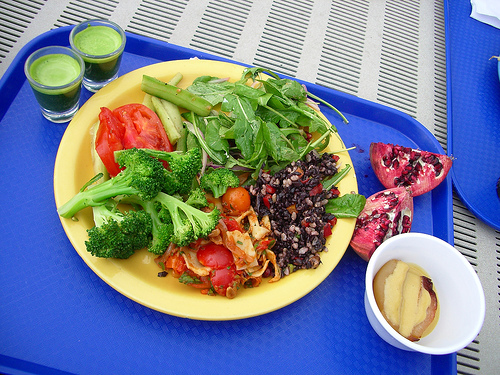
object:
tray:
[442, 0, 499, 231]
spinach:
[179, 66, 367, 219]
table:
[255, 1, 389, 56]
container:
[69, 19, 127, 93]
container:
[23, 44, 85, 123]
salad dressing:
[73, 25, 123, 85]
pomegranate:
[350, 184, 413, 262]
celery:
[140, 74, 214, 144]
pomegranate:
[368, 140, 453, 195]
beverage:
[27, 52, 82, 114]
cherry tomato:
[221, 186, 251, 216]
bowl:
[363, 232, 485, 353]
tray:
[0, 24, 456, 375]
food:
[56, 66, 453, 340]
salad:
[56, 66, 366, 299]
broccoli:
[56, 147, 239, 259]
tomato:
[95, 102, 175, 177]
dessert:
[371, 258, 437, 342]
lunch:
[24, 24, 452, 341]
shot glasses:
[24, 18, 126, 123]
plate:
[51, 58, 358, 322]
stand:
[29, 4, 439, 86]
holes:
[259, 25, 300, 60]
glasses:
[24, 19, 127, 124]